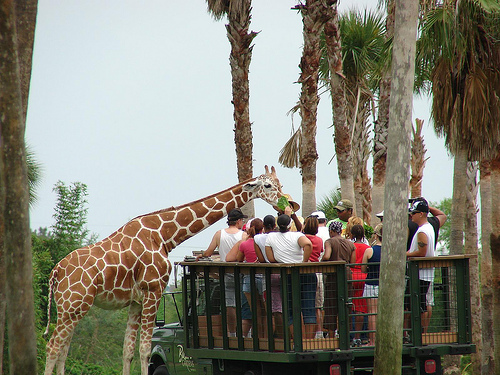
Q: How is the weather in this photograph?
A: It is cloudy.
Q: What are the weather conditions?
A: It is cloudy.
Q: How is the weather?
A: It is cloudy.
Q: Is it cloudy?
A: Yes, it is cloudy.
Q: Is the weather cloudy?
A: Yes, it is cloudy.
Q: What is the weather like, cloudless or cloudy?
A: It is cloudy.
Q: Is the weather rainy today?
A: No, it is cloudy.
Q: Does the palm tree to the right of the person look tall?
A: Yes, the palm is tall.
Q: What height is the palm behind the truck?
A: The palm is tall.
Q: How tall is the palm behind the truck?
A: The palm tree is tall.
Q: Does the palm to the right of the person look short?
A: No, the palm is tall.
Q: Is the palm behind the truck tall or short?
A: The palm tree is tall.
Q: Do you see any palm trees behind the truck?
A: Yes, there is a palm tree behind the truck.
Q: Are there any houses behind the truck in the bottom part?
A: No, there is a palm tree behind the truck.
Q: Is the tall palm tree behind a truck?
A: Yes, the palm is behind a truck.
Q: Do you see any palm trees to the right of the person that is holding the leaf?
A: Yes, there is a palm tree to the right of the person.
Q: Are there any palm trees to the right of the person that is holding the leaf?
A: Yes, there is a palm tree to the right of the person.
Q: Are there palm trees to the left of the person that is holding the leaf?
A: No, the palm tree is to the right of the person.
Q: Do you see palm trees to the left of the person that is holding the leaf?
A: No, the palm tree is to the right of the person.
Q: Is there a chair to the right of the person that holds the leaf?
A: No, there is a palm tree to the right of the person.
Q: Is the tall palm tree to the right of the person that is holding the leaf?
A: Yes, the palm is to the right of the person.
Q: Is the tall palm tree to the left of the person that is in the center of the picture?
A: No, the palm tree is to the right of the person.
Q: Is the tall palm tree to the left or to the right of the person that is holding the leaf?
A: The palm tree is to the right of the person.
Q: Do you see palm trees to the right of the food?
A: Yes, there is a palm tree to the right of the food.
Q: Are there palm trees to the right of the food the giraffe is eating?
A: Yes, there is a palm tree to the right of the food.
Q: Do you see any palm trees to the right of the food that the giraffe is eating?
A: Yes, there is a palm tree to the right of the food.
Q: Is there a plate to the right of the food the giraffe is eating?
A: No, there is a palm tree to the right of the food.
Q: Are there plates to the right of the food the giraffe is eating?
A: No, there is a palm tree to the right of the food.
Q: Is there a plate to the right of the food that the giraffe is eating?
A: No, there is a palm tree to the right of the food.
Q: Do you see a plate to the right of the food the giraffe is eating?
A: No, there is a palm tree to the right of the food.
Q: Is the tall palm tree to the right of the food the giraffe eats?
A: Yes, the palm tree is to the right of the food.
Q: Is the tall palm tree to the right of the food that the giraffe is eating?
A: Yes, the palm tree is to the right of the food.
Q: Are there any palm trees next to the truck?
A: Yes, there is a palm tree next to the truck.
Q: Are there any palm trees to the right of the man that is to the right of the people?
A: Yes, there is a palm tree to the right of the man.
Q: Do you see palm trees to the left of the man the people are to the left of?
A: No, the palm tree is to the right of the man.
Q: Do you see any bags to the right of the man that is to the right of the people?
A: No, there is a palm tree to the right of the man.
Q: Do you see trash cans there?
A: No, there are no trash cans.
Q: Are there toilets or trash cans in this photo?
A: No, there are no trash cans or toilets.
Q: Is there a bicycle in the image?
A: No, there are no bicycles.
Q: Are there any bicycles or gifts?
A: No, there are no bicycles or gifts.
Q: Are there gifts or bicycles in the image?
A: No, there are no bicycles or gifts.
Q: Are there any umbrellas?
A: No, there are no umbrellas.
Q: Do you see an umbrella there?
A: No, there are no umbrellas.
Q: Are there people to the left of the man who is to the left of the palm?
A: Yes, there are people to the left of the man.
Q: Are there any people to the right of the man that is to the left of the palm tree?
A: No, the people are to the left of the man.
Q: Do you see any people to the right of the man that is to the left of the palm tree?
A: No, the people are to the left of the man.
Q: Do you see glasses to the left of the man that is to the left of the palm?
A: No, there are people to the left of the man.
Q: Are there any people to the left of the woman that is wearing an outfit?
A: Yes, there are people to the left of the woman.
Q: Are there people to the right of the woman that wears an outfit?
A: No, the people are to the left of the woman.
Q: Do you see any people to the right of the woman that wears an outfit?
A: No, the people are to the left of the woman.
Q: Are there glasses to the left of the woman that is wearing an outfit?
A: No, there are people to the left of the woman.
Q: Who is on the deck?
A: The people are on the deck.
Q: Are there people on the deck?
A: Yes, there are people on the deck.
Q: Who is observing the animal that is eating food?
A: The people are observing the giraffe.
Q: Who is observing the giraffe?
A: The people are observing the giraffe.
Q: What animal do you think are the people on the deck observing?
A: The people are observing the giraffe.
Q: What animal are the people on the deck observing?
A: The people are observing the giraffe.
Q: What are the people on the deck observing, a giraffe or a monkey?
A: The people are observing a giraffe.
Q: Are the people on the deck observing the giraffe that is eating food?
A: Yes, the people are observing the giraffe.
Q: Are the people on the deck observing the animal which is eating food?
A: Yes, the people are observing the giraffe.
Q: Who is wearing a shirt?
A: The people are wearing a shirt.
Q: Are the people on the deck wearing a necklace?
A: No, the people are wearing a shirt.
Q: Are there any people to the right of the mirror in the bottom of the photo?
A: Yes, there are people to the right of the mirror.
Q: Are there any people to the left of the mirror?
A: No, the people are to the right of the mirror.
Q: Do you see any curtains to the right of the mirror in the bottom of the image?
A: No, there are people to the right of the mirror.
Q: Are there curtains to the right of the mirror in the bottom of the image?
A: No, there are people to the right of the mirror.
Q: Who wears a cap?
A: The people wear a cap.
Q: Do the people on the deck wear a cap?
A: Yes, the people wear a cap.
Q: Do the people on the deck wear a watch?
A: No, the people wear a cap.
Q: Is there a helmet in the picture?
A: No, there are no helmets.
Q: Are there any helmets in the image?
A: No, there are no helmets.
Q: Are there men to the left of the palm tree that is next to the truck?
A: Yes, there is a man to the left of the palm.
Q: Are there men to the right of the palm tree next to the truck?
A: No, the man is to the left of the palm.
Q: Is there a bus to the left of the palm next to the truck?
A: No, there is a man to the left of the palm tree.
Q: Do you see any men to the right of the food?
A: Yes, there is a man to the right of the food.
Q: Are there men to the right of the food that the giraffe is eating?
A: Yes, there is a man to the right of the food.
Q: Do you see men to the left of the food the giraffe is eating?
A: No, the man is to the right of the food.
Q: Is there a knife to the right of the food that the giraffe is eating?
A: No, there is a man to the right of the food.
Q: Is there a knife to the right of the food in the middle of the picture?
A: No, there is a man to the right of the food.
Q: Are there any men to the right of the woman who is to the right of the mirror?
A: Yes, there is a man to the right of the woman.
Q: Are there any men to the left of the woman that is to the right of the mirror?
A: No, the man is to the right of the woman.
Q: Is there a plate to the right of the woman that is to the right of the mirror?
A: No, there is a man to the right of the woman.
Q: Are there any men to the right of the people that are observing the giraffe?
A: Yes, there is a man to the right of the people.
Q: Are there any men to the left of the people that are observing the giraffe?
A: No, the man is to the right of the people.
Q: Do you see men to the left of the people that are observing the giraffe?
A: No, the man is to the right of the people.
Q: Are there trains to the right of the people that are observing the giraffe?
A: No, there is a man to the right of the people.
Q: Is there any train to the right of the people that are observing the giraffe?
A: No, there is a man to the right of the people.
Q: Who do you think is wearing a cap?
A: The man is wearing a cap.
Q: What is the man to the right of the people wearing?
A: The man is wearing a cap.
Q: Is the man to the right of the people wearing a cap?
A: Yes, the man is wearing a cap.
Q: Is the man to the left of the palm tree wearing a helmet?
A: No, the man is wearing a cap.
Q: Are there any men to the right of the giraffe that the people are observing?
A: Yes, there is a man to the right of the giraffe.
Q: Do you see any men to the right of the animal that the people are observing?
A: Yes, there is a man to the right of the giraffe.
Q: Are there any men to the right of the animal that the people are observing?
A: Yes, there is a man to the right of the giraffe.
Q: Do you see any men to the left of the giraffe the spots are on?
A: No, the man is to the right of the giraffe.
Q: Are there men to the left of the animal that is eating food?
A: No, the man is to the right of the giraffe.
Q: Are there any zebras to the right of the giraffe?
A: No, there is a man to the right of the giraffe.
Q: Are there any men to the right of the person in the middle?
A: Yes, there is a man to the right of the person.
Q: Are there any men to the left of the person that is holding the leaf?
A: No, the man is to the right of the person.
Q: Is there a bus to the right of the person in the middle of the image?
A: No, there is a man to the right of the person.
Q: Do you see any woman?
A: Yes, there is a woman.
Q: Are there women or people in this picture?
A: Yes, there is a woman.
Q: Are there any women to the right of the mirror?
A: Yes, there is a woman to the right of the mirror.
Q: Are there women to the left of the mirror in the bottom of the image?
A: No, the woman is to the right of the mirror.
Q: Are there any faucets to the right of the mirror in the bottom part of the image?
A: No, there is a woman to the right of the mirror.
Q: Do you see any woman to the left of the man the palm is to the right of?
A: Yes, there is a woman to the left of the man.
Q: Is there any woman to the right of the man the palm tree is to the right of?
A: No, the woman is to the left of the man.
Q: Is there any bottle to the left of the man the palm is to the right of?
A: No, there is a woman to the left of the man.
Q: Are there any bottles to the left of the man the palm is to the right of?
A: No, there is a woman to the left of the man.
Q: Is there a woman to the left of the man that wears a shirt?
A: Yes, there is a woman to the left of the man.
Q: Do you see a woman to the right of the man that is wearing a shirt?
A: No, the woman is to the left of the man.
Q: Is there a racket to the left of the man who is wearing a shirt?
A: No, there is a woman to the left of the man.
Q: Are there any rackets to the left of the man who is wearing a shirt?
A: No, there is a woman to the left of the man.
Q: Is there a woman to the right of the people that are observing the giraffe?
A: Yes, there is a woman to the right of the people.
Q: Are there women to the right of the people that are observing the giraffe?
A: Yes, there is a woman to the right of the people.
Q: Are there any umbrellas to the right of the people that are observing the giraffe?
A: No, there is a woman to the right of the people.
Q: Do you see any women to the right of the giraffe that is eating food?
A: Yes, there is a woman to the right of the giraffe.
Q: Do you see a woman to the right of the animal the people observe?
A: Yes, there is a woman to the right of the giraffe.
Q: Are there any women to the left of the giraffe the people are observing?
A: No, the woman is to the right of the giraffe.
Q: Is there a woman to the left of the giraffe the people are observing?
A: No, the woman is to the right of the giraffe.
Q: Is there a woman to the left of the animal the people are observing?
A: No, the woman is to the right of the giraffe.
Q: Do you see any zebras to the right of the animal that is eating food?
A: No, there is a woman to the right of the giraffe.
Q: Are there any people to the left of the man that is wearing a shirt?
A: Yes, there is a person to the left of the man.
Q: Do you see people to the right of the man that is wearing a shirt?
A: No, the person is to the left of the man.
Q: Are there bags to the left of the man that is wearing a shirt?
A: No, there is a person to the left of the man.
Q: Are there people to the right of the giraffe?
A: Yes, there is a person to the right of the giraffe.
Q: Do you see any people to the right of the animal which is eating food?
A: Yes, there is a person to the right of the giraffe.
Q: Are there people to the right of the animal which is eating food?
A: Yes, there is a person to the right of the giraffe.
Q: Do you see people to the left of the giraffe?
A: No, the person is to the right of the giraffe.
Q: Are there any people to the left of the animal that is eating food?
A: No, the person is to the right of the giraffe.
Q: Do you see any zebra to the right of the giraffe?
A: No, there is a person to the right of the giraffe.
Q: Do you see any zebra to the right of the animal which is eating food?
A: No, there is a person to the right of the giraffe.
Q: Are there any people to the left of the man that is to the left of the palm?
A: Yes, there is a person to the left of the man.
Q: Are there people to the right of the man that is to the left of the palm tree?
A: No, the person is to the left of the man.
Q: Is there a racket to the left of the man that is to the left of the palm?
A: No, there is a person to the left of the man.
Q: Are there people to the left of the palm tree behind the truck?
A: Yes, there is a person to the left of the palm tree.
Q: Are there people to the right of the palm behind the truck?
A: No, the person is to the left of the palm.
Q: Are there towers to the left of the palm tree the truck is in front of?
A: No, there is a person to the left of the palm tree.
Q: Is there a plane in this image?
A: No, there are no airplanes.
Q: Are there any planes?
A: No, there are no planes.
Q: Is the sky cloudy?
A: Yes, the sky is cloudy.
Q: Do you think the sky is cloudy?
A: Yes, the sky is cloudy.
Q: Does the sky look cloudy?
A: Yes, the sky is cloudy.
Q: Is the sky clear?
A: No, the sky is cloudy.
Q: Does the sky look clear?
A: No, the sky is cloudy.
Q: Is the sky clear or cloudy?
A: The sky is cloudy.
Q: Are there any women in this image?
A: Yes, there is a woman.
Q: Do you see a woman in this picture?
A: Yes, there is a woman.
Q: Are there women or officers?
A: Yes, there is a woman.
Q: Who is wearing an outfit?
A: The woman is wearing an outfit.